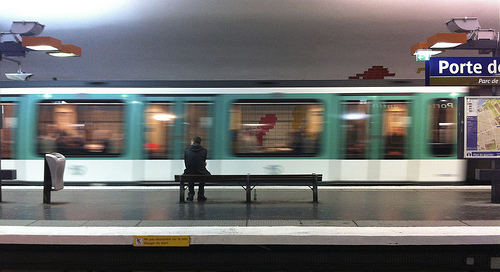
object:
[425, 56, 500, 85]
sign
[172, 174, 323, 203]
horse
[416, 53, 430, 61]
arrow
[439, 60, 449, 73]
letter p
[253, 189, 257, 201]
bottle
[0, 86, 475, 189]
train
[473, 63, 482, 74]
e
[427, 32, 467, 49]
light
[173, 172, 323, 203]
bench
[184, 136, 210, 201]
man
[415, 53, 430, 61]
sign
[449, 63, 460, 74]
letter o